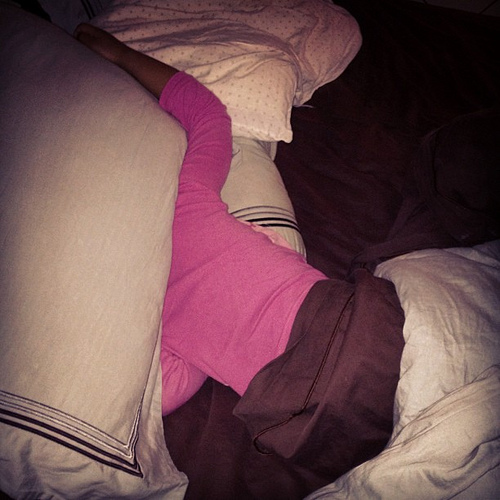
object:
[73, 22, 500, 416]
person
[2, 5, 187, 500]
pillow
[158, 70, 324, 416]
shirt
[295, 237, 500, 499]
coverlet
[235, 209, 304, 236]
trim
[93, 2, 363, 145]
material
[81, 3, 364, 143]
dots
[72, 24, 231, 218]
arm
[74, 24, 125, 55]
hand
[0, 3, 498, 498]
bed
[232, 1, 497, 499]
blanket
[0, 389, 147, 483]
lines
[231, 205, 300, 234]
lines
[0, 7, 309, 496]
pillow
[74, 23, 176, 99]
skin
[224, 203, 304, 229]
embellishment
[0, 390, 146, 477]
embellishment